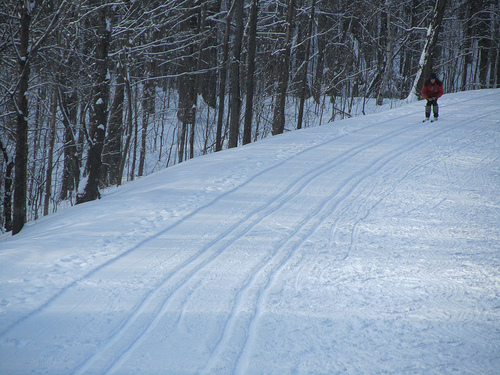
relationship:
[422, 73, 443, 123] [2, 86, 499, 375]
person in snow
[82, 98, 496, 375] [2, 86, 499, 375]
lines are in snow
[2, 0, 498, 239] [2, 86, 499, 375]
trees are in snow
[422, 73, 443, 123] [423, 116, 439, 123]
person has skis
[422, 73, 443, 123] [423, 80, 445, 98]
person wearing jacket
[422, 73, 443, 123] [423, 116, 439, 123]
person wearing skis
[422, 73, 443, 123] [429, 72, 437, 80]
person wearing hat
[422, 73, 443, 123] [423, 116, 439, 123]
person on skis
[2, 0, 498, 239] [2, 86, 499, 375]
trees are next to snow